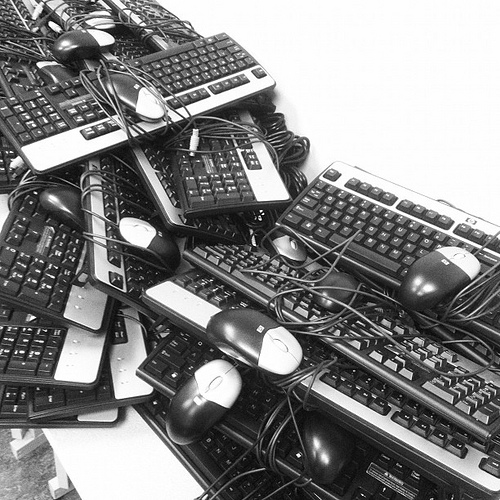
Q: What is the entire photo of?
A: Keyboards and mice.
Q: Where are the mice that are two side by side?
A: The bottom in the middle.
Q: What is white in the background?
A: Wall.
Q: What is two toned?
A: The computer mouse.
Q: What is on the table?
A: Keyboard.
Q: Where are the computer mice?
A: In a pile.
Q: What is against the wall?
A: Table.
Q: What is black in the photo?
A: Computer.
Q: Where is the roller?
A: On the mouse.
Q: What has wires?
A: The electronic.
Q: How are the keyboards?
A: Stacked.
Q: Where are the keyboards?
A: On the table.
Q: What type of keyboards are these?
A: Computer.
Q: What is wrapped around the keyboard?
A: Mouse.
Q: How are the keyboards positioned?
A: Stacked.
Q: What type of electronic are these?
A: Keyboards.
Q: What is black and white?
A: Keyboards and mice.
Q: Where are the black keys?
A: On the keyboard.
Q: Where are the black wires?
A: On the keyboards.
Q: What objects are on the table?
A: Keyboards.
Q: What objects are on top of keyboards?
A: Mouses.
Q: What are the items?
A: Keyboards.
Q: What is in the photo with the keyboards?
A: Mouse.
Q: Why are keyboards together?
A: Storage.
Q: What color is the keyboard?
A: Black.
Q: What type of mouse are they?
A: Wired.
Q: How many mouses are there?
A: About Ten.